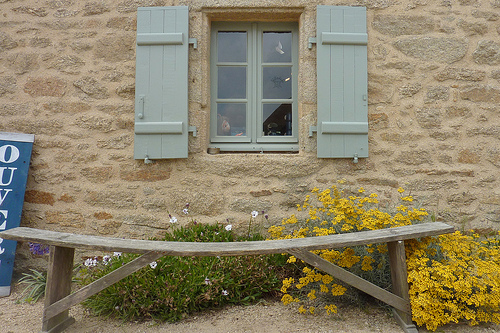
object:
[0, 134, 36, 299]
sign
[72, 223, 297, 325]
bush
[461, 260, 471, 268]
flowers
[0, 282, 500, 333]
ground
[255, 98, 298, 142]
window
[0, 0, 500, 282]
house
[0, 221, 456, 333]
bench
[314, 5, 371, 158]
shutters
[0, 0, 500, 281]
wall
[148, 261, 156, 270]
flower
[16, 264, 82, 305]
grass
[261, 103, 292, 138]
shadow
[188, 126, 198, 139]
hinges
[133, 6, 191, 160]
shutter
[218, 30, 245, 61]
pane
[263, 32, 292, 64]
pane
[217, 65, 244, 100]
pane